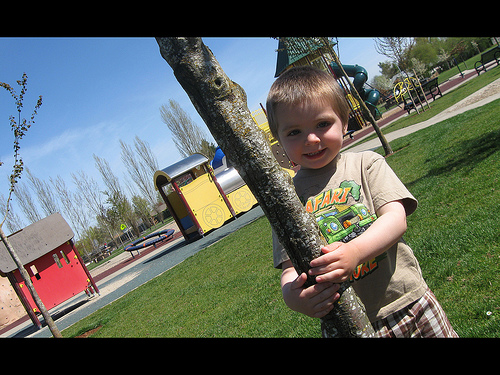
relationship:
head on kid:
[261, 59, 355, 171] [263, 69, 459, 337]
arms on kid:
[264, 201, 345, 320] [263, 69, 459, 337]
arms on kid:
[304, 159, 413, 284] [263, 69, 459, 337]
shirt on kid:
[261, 140, 438, 330] [263, 69, 459, 337]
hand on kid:
[280, 266, 344, 324] [255, 57, 467, 343]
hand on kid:
[309, 230, 366, 290] [255, 57, 467, 343]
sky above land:
[4, 38, 414, 261] [2, 35, 498, 336]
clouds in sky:
[7, 119, 113, 168] [4, 38, 414, 261]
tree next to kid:
[155, 37, 375, 335] [263, 69, 459, 337]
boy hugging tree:
[261, 62, 460, 336] [155, 37, 375, 335]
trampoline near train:
[125, 226, 181, 256] [86, 199, 169, 258]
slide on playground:
[324, 54, 385, 108] [258, 37, 498, 166]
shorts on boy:
[315, 278, 461, 345] [261, 62, 460, 336]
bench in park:
[474, 47, 495, 76] [59, 39, 498, 339]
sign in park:
[116, 218, 128, 231] [59, 39, 498, 339]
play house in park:
[2, 212, 104, 333] [59, 39, 498, 339]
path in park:
[345, 75, 498, 159] [59, 39, 498, 339]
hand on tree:
[280, 271, 340, 318] [155, 37, 375, 335]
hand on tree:
[307, 241, 361, 283] [155, 37, 375, 335]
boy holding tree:
[261, 62, 460, 336] [155, 37, 375, 335]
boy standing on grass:
[261, 62, 460, 336] [48, 97, 485, 337]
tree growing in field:
[0, 70, 63, 335] [47, 95, 485, 335]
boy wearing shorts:
[261, 62, 460, 336] [319, 289, 459, 336]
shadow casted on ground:
[399, 128, 485, 185] [0, 42, 483, 334]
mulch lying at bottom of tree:
[70, 322, 102, 336] [0, 70, 63, 335]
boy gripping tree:
[261, 62, 460, 336] [155, 37, 375, 335]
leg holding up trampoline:
[128, 250, 136, 259] [121, 227, 175, 258]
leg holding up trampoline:
[134, 249, 141, 257] [121, 227, 175, 258]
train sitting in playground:
[150, 149, 295, 243] [0, 36, 484, 339]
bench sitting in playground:
[470, 44, 484, 75] [0, 36, 484, 339]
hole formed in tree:
[211, 76, 222, 87] [155, 37, 375, 335]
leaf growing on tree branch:
[18, 157, 23, 162] [0, 70, 43, 226]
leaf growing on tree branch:
[17, 175, 22, 179] [0, 70, 43, 226]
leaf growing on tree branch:
[10, 187, 16, 192] [0, 70, 43, 226]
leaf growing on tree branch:
[23, 87, 28, 91] [0, 70, 43, 226]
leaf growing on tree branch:
[10, 115, 15, 119] [0, 70, 43, 226]